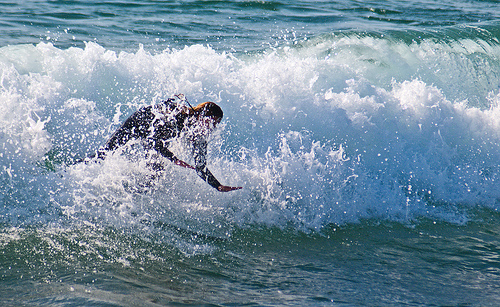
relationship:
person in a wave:
[83, 91, 247, 202] [34, 43, 467, 94]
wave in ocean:
[34, 43, 467, 94] [0, 1, 498, 299]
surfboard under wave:
[71, 175, 217, 256] [34, 43, 467, 94]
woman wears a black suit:
[83, 91, 247, 202] [131, 112, 176, 135]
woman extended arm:
[83, 91, 247, 202] [146, 129, 224, 192]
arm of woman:
[146, 129, 224, 192] [83, 91, 247, 202]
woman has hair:
[83, 91, 247, 202] [191, 99, 228, 128]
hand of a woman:
[218, 181, 244, 197] [83, 91, 247, 202]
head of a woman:
[190, 99, 226, 128] [83, 91, 247, 202]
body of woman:
[108, 99, 197, 150] [83, 91, 247, 202]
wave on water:
[34, 43, 467, 94] [76, 0, 288, 45]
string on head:
[175, 93, 197, 115] [190, 99, 226, 128]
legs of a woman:
[88, 127, 168, 194] [83, 91, 247, 202]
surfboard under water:
[71, 175, 217, 256] [76, 0, 288, 45]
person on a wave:
[83, 91, 247, 202] [34, 43, 467, 94]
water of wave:
[76, 0, 288, 45] [34, 43, 467, 94]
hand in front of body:
[218, 181, 244, 197] [108, 99, 197, 150]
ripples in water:
[146, 239, 298, 284] [76, 0, 288, 45]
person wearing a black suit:
[83, 91, 247, 202] [131, 112, 176, 135]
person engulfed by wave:
[83, 91, 247, 202] [34, 43, 467, 94]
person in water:
[83, 91, 247, 202] [76, 0, 288, 45]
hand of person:
[218, 181, 244, 197] [83, 91, 247, 202]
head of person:
[190, 99, 226, 128] [83, 91, 247, 202]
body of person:
[108, 99, 197, 150] [83, 91, 247, 202]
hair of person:
[209, 104, 220, 112] [83, 91, 247, 202]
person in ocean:
[83, 91, 247, 202] [0, 1, 498, 299]